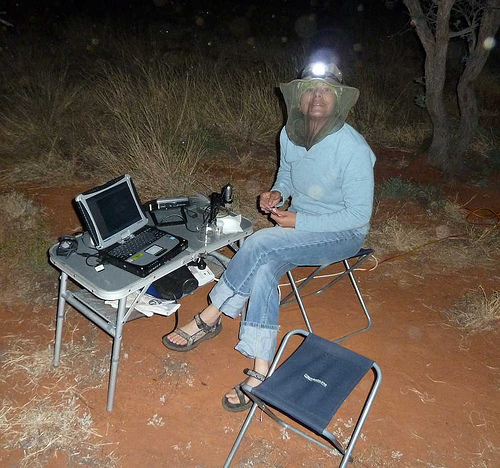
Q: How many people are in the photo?
A: One.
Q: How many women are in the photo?
A: One.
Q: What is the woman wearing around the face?
A: Insect net.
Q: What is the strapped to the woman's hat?
A: Light.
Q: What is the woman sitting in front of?
A: Laptop on desk.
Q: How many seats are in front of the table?
A: Two.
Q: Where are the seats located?
A: Patch of clay ground.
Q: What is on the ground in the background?
A: Yellow brush.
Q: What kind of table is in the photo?
A: Folding table.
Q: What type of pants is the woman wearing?
A: Blue jeans.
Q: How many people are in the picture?
A: 1.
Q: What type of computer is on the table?
A: Laptop.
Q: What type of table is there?
A: A folding table.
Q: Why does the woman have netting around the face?
A: To keep away bugs.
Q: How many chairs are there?
A: 2.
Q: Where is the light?
A: On woman's head.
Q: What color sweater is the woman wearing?
A: Light blue.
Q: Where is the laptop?
A: On folding table.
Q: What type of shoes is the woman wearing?
A: Sandals.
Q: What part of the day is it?
A: Night.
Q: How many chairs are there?
A: 2.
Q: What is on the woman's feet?
A: Sandals.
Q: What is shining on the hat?
A: A light.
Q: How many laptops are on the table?
A: 1.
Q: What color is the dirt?
A: Brown.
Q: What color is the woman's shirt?
A: Blue.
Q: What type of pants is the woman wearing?
A: Jeans.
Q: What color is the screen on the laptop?
A: Black.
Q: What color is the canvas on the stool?
A: Navy.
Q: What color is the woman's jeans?
A: Blue.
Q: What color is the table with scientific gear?
A: Silver.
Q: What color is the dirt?
A: Brown.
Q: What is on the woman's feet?
A: Sandals.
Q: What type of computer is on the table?
A: Laptop.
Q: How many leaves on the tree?
A: Zero.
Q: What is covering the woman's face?
A: Netting.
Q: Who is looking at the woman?
A: The photographer.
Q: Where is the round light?
A: On the woman's hat.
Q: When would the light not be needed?
A: In the daytime.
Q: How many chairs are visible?
A: Two.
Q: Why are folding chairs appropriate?
A: They transport easily.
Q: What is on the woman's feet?
A: Sandals.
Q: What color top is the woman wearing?
A: Blue.